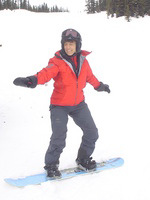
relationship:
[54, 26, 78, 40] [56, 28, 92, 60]
goggles are pushed up on womans head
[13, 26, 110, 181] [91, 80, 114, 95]
person has a  glove on her hand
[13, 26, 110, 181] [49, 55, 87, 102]
person wearing a jacket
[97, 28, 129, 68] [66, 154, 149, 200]
snow on ground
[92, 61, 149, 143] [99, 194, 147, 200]
snow color white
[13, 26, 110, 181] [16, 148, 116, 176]
person standing on a snowboard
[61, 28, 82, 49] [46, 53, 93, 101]
helmet has on pants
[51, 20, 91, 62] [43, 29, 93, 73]
head of woman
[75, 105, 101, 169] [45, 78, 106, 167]
leg of woman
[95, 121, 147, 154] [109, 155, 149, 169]
snow covered ground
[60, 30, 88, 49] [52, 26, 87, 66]
helmet on head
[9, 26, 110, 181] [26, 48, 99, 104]
person wearing jacket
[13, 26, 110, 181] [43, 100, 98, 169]
person wearing pants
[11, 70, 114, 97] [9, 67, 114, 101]
gloves on hands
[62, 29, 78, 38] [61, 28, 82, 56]
goggles on head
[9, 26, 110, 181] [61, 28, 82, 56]
person has head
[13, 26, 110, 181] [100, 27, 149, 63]
person snowboarding on snow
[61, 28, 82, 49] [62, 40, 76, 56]
helmet on head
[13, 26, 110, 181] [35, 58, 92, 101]
person wearing jacket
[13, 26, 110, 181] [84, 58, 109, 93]
person has arm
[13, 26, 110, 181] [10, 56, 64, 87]
person has arm